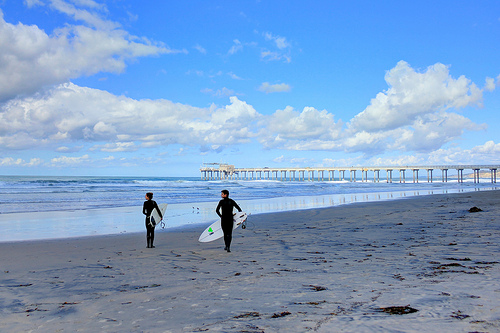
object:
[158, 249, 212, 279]
foot steps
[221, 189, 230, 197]
dark hair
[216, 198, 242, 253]
wetsuit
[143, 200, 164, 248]
wet suit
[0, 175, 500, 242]
ocean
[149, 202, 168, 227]
board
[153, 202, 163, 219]
surfer's arm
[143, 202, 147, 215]
surfer's arm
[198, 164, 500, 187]
pier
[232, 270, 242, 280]
footprint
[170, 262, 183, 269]
footprint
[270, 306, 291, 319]
footprint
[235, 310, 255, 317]
footprint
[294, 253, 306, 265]
footprint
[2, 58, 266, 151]
cloud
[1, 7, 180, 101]
cloud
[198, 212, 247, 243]
board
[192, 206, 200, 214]
birds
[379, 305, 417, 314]
seaweed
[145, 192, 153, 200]
woman's head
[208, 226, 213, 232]
sticker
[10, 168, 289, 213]
water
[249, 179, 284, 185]
waves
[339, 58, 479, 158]
cloud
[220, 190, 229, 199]
head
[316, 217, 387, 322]
sand area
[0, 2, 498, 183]
sky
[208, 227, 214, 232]
green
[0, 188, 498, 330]
sand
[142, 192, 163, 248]
surfer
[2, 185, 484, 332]
beach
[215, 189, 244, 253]
man